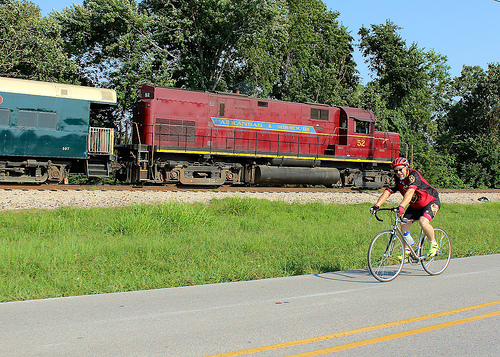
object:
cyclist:
[368, 157, 440, 263]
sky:
[26, 0, 500, 147]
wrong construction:
[400, 190, 439, 210]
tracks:
[0, 183, 500, 193]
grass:
[0, 197, 500, 302]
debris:
[478, 197, 490, 202]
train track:
[2, 164, 499, 201]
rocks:
[0, 189, 500, 212]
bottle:
[403, 231, 415, 246]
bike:
[368, 207, 451, 282]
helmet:
[391, 157, 409, 170]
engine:
[166, 162, 236, 185]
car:
[0, 77, 118, 159]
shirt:
[385, 168, 438, 209]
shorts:
[403, 197, 440, 224]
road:
[0, 254, 500, 357]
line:
[209, 301, 498, 357]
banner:
[210, 116, 316, 134]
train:
[0, 77, 400, 189]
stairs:
[86, 154, 111, 178]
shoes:
[397, 242, 439, 261]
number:
[355, 136, 368, 150]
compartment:
[0, 92, 90, 160]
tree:
[0, 0, 500, 191]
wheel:
[367, 230, 405, 282]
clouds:
[414, 34, 465, 60]